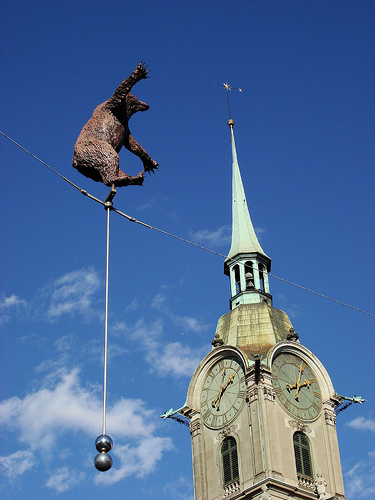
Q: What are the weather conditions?
A: It is clear.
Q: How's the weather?
A: It is clear.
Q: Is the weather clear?
A: Yes, it is clear.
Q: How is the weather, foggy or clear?
A: It is clear.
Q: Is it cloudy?
A: No, it is clear.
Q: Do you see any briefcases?
A: No, there are no briefcases.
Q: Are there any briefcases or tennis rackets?
A: No, there are no briefcases or tennis rackets.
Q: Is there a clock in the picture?
A: Yes, there is a clock.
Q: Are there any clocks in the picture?
A: Yes, there is a clock.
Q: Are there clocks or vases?
A: Yes, there is a clock.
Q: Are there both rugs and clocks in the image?
A: No, there is a clock but no rugs.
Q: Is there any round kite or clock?
A: Yes, there is a round clock.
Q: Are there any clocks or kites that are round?
A: Yes, the clock is round.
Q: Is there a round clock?
A: Yes, there is a round clock.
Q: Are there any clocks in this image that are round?
A: Yes, there is a clock that is round.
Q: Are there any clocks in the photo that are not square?
A: Yes, there is a round clock.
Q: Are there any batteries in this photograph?
A: No, there are no batteries.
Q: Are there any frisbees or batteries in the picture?
A: No, there are no batteries or frisbees.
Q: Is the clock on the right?
A: Yes, the clock is on the right of the image.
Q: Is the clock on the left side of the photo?
A: No, the clock is on the right of the image.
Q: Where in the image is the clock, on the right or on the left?
A: The clock is on the right of the image.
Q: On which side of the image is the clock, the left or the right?
A: The clock is on the right of the image.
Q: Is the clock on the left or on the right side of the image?
A: The clock is on the right of the image.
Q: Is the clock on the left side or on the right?
A: The clock is on the right of the image.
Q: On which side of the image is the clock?
A: The clock is on the right of the image.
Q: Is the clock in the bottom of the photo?
A: Yes, the clock is in the bottom of the image.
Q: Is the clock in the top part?
A: No, the clock is in the bottom of the image.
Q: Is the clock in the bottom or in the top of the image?
A: The clock is in the bottom of the image.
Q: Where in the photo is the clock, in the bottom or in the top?
A: The clock is in the bottom of the image.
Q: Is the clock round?
A: Yes, the clock is round.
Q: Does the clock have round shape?
A: Yes, the clock is round.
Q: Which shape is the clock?
A: The clock is round.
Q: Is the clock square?
A: No, the clock is round.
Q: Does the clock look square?
A: No, the clock is round.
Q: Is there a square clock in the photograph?
A: No, there is a clock but it is round.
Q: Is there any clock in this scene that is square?
A: No, there is a clock but it is round.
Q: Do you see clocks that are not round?
A: No, there is a clock but it is round.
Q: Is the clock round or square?
A: The clock is round.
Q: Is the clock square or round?
A: The clock is round.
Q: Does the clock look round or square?
A: The clock is round.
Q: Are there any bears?
A: Yes, there is a bear.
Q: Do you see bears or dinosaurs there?
A: Yes, there is a bear.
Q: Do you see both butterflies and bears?
A: No, there is a bear but no butterflies.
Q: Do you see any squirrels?
A: No, there are no squirrels.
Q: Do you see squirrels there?
A: No, there are no squirrels.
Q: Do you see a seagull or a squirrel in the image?
A: No, there are no squirrels or seagulls.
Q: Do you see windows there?
A: Yes, there is a window.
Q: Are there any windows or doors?
A: Yes, there is a window.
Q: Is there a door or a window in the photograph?
A: Yes, there is a window.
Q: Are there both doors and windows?
A: No, there is a window but no doors.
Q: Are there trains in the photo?
A: No, there are no trains.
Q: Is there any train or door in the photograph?
A: No, there are no trains or doors.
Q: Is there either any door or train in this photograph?
A: No, there are no trains or doors.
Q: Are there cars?
A: No, there are no cars.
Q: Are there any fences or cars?
A: No, there are no cars or fences.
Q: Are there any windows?
A: Yes, there are windows.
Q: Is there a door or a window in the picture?
A: Yes, there are windows.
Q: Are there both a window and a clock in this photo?
A: Yes, there are both a window and a clock.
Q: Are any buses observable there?
A: No, there are no buses.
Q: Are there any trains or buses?
A: No, there are no buses or trains.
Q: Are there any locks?
A: No, there are no locks.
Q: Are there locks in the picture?
A: No, there are no locks.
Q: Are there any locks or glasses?
A: No, there are no locks or glasses.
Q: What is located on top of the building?
A: The cross is on top of the building.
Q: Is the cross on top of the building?
A: Yes, the cross is on top of the building.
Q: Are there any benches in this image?
A: No, there are no benches.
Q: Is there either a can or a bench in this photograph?
A: No, there are no benches or cans.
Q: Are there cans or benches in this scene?
A: No, there are no benches or cans.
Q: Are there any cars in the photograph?
A: No, there are no cars.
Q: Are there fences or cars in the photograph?
A: No, there are no cars or fences.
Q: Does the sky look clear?
A: Yes, the sky is clear.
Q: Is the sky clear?
A: Yes, the sky is clear.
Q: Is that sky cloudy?
A: No, the sky is clear.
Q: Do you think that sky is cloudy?
A: No, the sky is clear.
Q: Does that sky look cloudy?
A: No, the sky is clear.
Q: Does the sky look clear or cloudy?
A: The sky is clear.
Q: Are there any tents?
A: No, there are no tents.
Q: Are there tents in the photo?
A: No, there are no tents.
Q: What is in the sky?
A: The clouds are in the sky.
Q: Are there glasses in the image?
A: No, there are no glasses.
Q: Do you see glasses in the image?
A: No, there are no glasses.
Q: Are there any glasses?
A: No, there are no glasses.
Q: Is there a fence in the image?
A: No, there are no fences.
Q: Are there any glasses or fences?
A: No, there are no fences or glasses.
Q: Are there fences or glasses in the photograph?
A: No, there are no fences or glasses.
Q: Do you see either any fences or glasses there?
A: No, there are no fences or glasses.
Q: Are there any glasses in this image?
A: No, there are no glasses.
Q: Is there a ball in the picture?
A: Yes, there is a ball.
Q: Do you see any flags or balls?
A: Yes, there is a ball.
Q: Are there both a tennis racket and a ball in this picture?
A: No, there is a ball but no rackets.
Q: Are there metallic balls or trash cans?
A: Yes, there is a metal ball.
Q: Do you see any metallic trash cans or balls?
A: Yes, there is a metal ball.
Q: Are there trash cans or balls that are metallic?
A: Yes, the ball is metallic.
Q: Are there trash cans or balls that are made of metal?
A: Yes, the ball is made of metal.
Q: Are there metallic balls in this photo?
A: Yes, there is a metal ball.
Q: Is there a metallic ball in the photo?
A: Yes, there is a metal ball.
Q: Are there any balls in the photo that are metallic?
A: Yes, there is a ball that is metallic.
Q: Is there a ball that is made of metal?
A: Yes, there is a ball that is made of metal.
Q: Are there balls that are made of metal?
A: Yes, there is a ball that is made of metal.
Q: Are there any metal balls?
A: Yes, there is a ball that is made of metal.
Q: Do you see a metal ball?
A: Yes, there is a ball that is made of metal.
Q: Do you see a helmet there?
A: No, there are no helmets.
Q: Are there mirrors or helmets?
A: No, there are no helmets or mirrors.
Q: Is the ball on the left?
A: Yes, the ball is on the left of the image.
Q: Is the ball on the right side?
A: No, the ball is on the left of the image.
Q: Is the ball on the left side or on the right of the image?
A: The ball is on the left of the image.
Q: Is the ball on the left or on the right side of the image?
A: The ball is on the left of the image.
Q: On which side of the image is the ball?
A: The ball is on the left of the image.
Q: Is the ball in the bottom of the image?
A: Yes, the ball is in the bottom of the image.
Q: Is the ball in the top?
A: No, the ball is in the bottom of the image.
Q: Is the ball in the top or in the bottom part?
A: The ball is in the bottom of the image.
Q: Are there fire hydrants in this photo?
A: No, there are no fire hydrants.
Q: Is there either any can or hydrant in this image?
A: No, there are no fire hydrants or cans.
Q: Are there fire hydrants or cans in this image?
A: No, there are no fire hydrants or cans.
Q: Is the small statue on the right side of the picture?
A: Yes, the statue is on the right of the image.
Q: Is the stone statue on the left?
A: No, the statue is on the right of the image.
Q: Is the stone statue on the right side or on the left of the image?
A: The statue is on the right of the image.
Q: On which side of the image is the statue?
A: The statue is on the right of the image.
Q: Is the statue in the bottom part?
A: Yes, the statue is in the bottom of the image.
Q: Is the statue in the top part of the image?
A: No, the statue is in the bottom of the image.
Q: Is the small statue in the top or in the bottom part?
A: The statue is in the bottom of the image.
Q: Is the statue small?
A: Yes, the statue is small.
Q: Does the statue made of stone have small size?
A: Yes, the statue is small.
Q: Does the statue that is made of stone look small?
A: Yes, the statue is small.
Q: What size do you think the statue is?
A: The statue is small.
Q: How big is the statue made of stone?
A: The statue is small.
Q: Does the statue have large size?
A: No, the statue is small.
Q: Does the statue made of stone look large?
A: No, the statue is small.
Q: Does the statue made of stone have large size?
A: No, the statue is small.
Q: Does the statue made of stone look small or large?
A: The statue is small.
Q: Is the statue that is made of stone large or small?
A: The statue is small.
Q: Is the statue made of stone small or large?
A: The statue is small.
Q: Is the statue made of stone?
A: Yes, the statue is made of stone.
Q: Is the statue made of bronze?
A: No, the statue is made of stone.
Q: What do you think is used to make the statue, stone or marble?
A: The statue is made of stone.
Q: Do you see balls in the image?
A: Yes, there is a ball.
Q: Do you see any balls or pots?
A: Yes, there is a ball.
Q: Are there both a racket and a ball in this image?
A: No, there is a ball but no rackets.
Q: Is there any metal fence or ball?
A: Yes, there is a metal ball.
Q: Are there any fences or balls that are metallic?
A: Yes, the ball is metallic.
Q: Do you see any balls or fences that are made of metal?
A: Yes, the ball is made of metal.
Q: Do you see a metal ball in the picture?
A: Yes, there is a metal ball.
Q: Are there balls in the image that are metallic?
A: Yes, there is a ball that is metallic.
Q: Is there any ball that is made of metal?
A: Yes, there is a ball that is made of metal.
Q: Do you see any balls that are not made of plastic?
A: Yes, there is a ball that is made of metal.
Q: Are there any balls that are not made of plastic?
A: Yes, there is a ball that is made of metal.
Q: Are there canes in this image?
A: No, there are no canes.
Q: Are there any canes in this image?
A: No, there are no canes.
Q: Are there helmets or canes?
A: No, there are no canes or helmets.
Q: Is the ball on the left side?
A: Yes, the ball is on the left of the image.